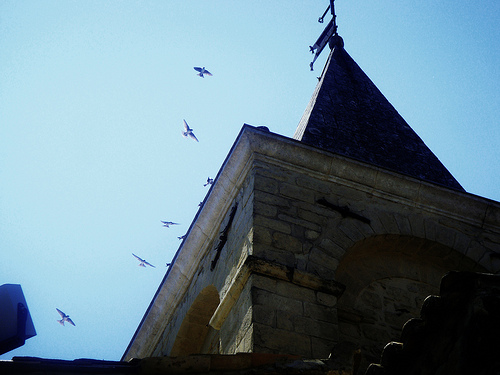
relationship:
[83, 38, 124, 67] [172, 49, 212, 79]
sky in birds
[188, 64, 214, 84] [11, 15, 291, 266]
bird flying in sky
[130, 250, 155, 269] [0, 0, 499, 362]
bird flying in sky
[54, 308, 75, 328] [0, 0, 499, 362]
bird flying in sky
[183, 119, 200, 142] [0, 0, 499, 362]
bird flying in sky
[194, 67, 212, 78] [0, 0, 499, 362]
bird flying in sky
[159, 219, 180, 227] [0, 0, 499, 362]
bird flying in sky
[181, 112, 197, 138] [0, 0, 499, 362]
bird flying in sky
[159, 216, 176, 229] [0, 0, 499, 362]
bird flying in sky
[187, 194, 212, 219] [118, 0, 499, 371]
bird sitting on building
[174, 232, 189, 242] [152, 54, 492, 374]
bird sitting on building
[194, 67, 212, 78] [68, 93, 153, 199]
bird in sky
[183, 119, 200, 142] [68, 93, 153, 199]
bird in sky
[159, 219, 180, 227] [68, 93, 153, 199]
bird in sky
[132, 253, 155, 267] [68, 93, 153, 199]
bird in sky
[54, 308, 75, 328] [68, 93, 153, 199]
bird in sky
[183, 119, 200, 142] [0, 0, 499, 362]
bird in sky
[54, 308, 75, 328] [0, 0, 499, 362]
bird in sky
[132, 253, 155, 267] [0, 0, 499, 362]
bird in sky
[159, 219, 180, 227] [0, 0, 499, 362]
bird in sky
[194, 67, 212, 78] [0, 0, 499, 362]
bird in sky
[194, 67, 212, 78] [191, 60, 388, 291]
bird above building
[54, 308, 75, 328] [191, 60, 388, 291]
bird above building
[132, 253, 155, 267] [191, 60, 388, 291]
bird above building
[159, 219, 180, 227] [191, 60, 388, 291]
bird above building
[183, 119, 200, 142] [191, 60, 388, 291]
bird above building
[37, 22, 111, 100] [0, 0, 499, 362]
white clouds in sky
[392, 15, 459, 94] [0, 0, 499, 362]
clouds in sky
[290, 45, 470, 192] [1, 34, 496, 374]
steeple on building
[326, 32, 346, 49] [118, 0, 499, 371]
ball on building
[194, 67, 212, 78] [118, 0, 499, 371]
bird flying around building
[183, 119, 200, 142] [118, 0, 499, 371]
bird flying around building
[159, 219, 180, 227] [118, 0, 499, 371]
bird flying around building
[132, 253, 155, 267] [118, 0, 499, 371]
bird flying around building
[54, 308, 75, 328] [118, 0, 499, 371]
bird flying around building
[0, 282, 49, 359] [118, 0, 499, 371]
light fixture focused on building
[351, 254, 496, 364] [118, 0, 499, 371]
arch on building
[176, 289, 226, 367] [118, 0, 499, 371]
arch on building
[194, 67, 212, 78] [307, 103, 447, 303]
bird flying over building